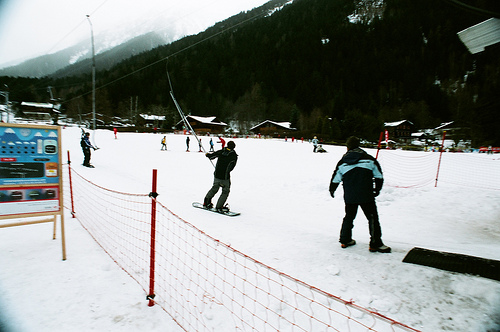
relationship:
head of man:
[345, 137, 361, 147] [327, 146, 401, 258]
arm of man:
[321, 168, 362, 210] [327, 146, 401, 258]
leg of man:
[338, 214, 366, 238] [327, 146, 401, 258]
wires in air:
[115, 44, 206, 83] [115, 45, 221, 93]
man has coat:
[328, 136, 391, 254] [313, 149, 383, 186]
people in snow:
[138, 118, 258, 174] [115, 150, 184, 188]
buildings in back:
[469, 39, 500, 111] [447, 25, 497, 98]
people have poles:
[138, 118, 258, 174] [193, 140, 232, 179]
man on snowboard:
[327, 146, 401, 258] [182, 196, 242, 223]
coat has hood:
[328, 149, 384, 204] [334, 148, 363, 156]